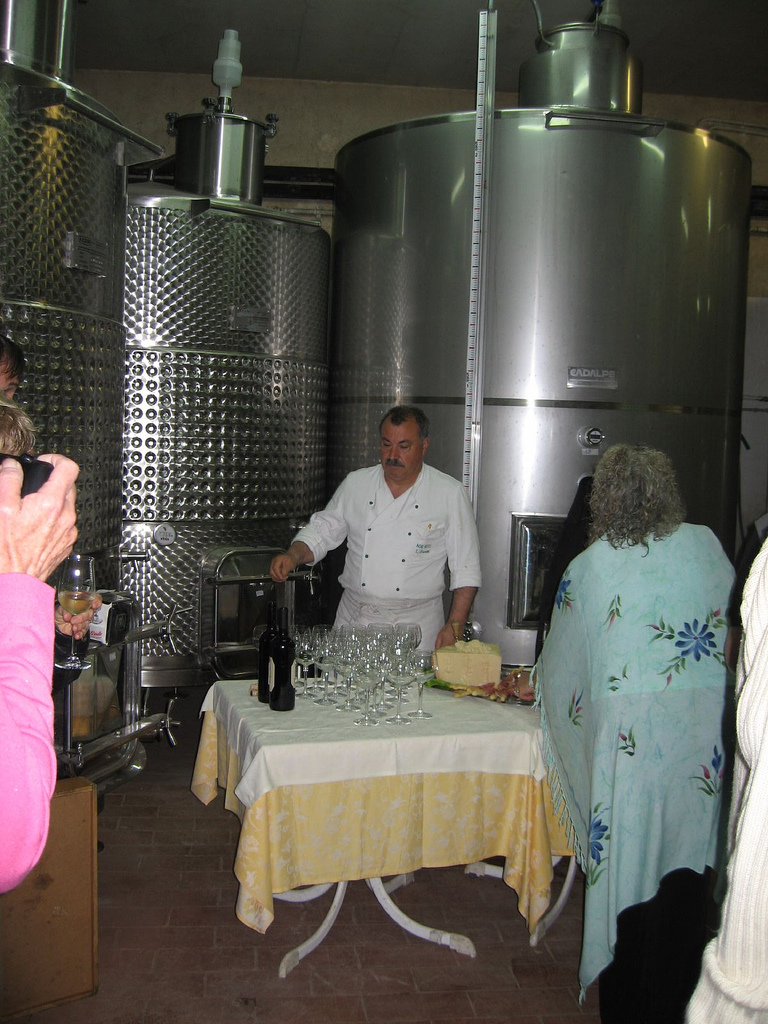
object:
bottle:
[267, 608, 296, 711]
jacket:
[292, 466, 483, 601]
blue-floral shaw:
[528, 526, 736, 1010]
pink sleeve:
[4, 566, 62, 892]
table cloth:
[195, 707, 581, 937]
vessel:
[335, 639, 361, 714]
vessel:
[315, 631, 338, 707]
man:
[269, 404, 482, 736]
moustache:
[385, 459, 407, 468]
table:
[189, 660, 568, 968]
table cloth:
[186, 649, 577, 812]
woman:
[537, 446, 754, 1022]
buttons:
[411, 501, 421, 513]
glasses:
[350, 644, 388, 727]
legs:
[278, 871, 350, 980]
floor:
[98, 698, 607, 1024]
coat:
[275, 458, 478, 631]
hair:
[587, 443, 685, 556]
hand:
[0, 448, 84, 585]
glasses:
[408, 651, 441, 723]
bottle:
[258, 601, 283, 704]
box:
[0, 771, 104, 1022]